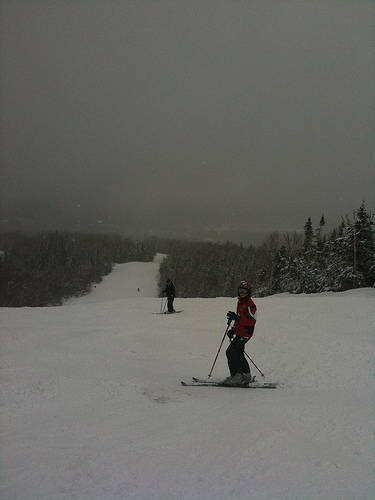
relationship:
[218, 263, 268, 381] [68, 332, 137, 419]
kid in snow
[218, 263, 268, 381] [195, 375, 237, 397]
kid on board